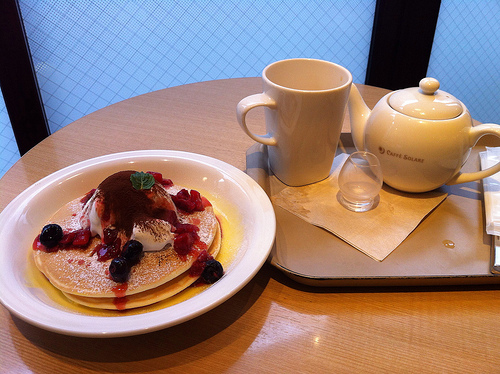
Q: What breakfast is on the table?
A: Pancakes.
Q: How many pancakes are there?
A: Two.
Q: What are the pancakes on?
A: Plate.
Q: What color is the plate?
A: White.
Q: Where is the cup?
A: On tray.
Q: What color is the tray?
A: Brown.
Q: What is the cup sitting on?
A: Napkin.